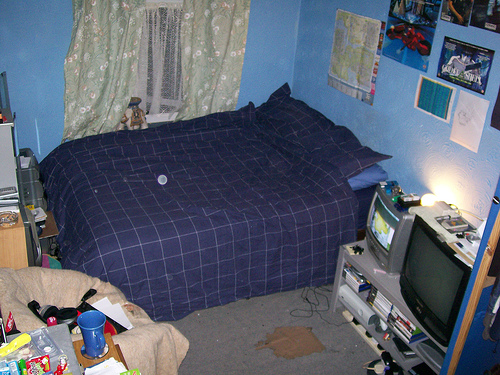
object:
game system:
[336, 270, 447, 374]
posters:
[332, 2, 500, 151]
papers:
[446, 88, 492, 154]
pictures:
[378, 0, 446, 73]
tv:
[398, 199, 487, 346]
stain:
[253, 324, 327, 359]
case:
[254, 82, 337, 142]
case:
[291, 125, 392, 181]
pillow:
[255, 82, 395, 190]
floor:
[156, 282, 385, 375]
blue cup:
[76, 309, 108, 356]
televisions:
[364, 188, 415, 274]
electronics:
[357, 181, 489, 307]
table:
[336, 215, 470, 369]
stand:
[324, 232, 456, 374]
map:
[328, 8, 387, 98]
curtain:
[65, 0, 142, 139]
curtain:
[174, 0, 243, 125]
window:
[73, 0, 245, 125]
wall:
[0, 0, 497, 231]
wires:
[288, 280, 349, 337]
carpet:
[161, 297, 343, 373]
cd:
[74, 332, 115, 358]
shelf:
[339, 238, 445, 355]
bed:
[38, 82, 394, 323]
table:
[71, 329, 122, 372]